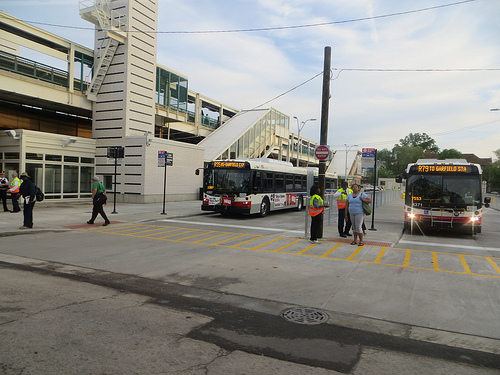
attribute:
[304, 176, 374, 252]
people — standing on crossing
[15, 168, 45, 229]
man — dressed in black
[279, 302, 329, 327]
cover — round, man hole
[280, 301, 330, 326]
cover — man hole, steel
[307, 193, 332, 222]
vest — orange, green